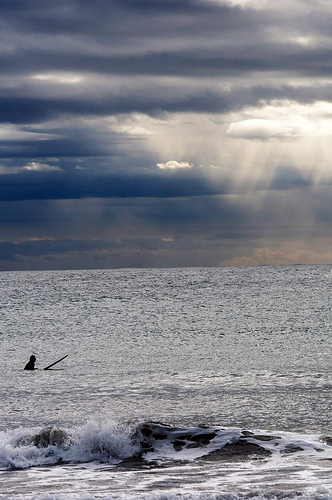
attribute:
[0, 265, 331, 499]
water — dark, dark blue, dark brown, dark colored, large, blue, wavy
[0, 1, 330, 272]
clouds — gray, dark, white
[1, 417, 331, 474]
wave — crashing, white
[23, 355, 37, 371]
surfer — sitting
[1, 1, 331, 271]
sky — cloudy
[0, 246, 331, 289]
horizon — distant